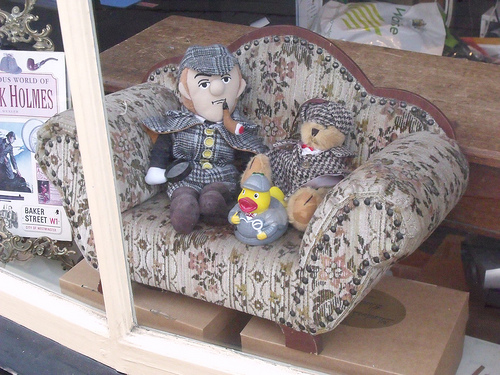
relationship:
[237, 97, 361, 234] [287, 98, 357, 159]
bear has hat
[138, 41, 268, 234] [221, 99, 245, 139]
sherlock holmes has pipe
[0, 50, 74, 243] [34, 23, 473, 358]
book near couch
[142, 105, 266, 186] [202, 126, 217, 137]
coat has buton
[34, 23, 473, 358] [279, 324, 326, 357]
couch has foot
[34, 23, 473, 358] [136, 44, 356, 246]
couch has stuffed animals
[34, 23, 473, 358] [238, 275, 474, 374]
couch on top of box